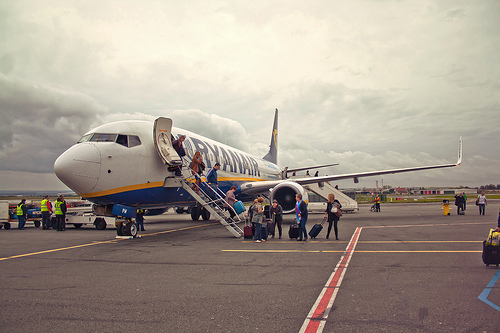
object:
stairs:
[180, 167, 247, 239]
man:
[38, 194, 53, 229]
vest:
[40, 200, 47, 211]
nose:
[51, 142, 100, 195]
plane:
[50, 107, 467, 241]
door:
[151, 116, 186, 169]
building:
[413, 185, 482, 195]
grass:
[357, 194, 498, 203]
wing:
[238, 133, 466, 196]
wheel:
[112, 220, 137, 236]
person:
[324, 192, 345, 242]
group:
[241, 191, 345, 242]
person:
[266, 198, 286, 241]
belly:
[96, 190, 266, 204]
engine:
[268, 181, 306, 216]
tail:
[260, 107, 281, 164]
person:
[291, 191, 312, 242]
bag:
[287, 220, 305, 242]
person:
[250, 197, 264, 244]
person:
[220, 185, 241, 217]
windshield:
[82, 130, 145, 148]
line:
[294, 226, 364, 332]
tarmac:
[0, 202, 500, 332]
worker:
[14, 198, 29, 231]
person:
[204, 161, 221, 198]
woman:
[189, 148, 207, 193]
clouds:
[0, 3, 497, 185]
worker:
[53, 196, 66, 230]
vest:
[53, 201, 64, 215]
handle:
[319, 215, 326, 225]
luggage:
[308, 220, 326, 240]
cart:
[0, 197, 43, 230]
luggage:
[26, 206, 39, 218]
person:
[172, 132, 191, 158]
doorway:
[161, 130, 192, 169]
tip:
[455, 130, 465, 165]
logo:
[272, 125, 279, 148]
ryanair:
[183, 136, 263, 179]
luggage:
[266, 218, 275, 236]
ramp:
[302, 173, 359, 210]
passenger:
[314, 169, 321, 178]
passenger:
[291, 171, 297, 178]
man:
[473, 191, 489, 215]